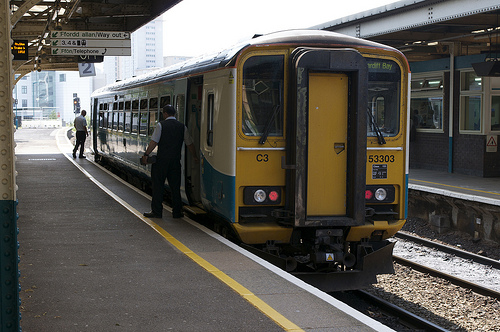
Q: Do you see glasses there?
A: No, there are no glasses.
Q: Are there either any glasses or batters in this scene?
A: No, there are no glasses or batters.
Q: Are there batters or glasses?
A: No, there are no glasses or batters.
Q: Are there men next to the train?
A: Yes, there is a man next to the train.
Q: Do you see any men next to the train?
A: Yes, there is a man next to the train.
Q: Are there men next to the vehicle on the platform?
A: Yes, there is a man next to the train.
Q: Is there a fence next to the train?
A: No, there is a man next to the train.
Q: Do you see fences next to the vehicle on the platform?
A: No, there is a man next to the train.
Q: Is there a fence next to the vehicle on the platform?
A: No, there is a man next to the train.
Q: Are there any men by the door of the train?
A: Yes, there is a man by the door.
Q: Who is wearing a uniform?
A: The man is wearing a uniform.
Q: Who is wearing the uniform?
A: The man is wearing a uniform.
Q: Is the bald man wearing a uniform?
A: Yes, the man is wearing a uniform.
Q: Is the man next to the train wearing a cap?
A: No, the man is wearing a uniform.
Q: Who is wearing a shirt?
A: The man is wearing a shirt.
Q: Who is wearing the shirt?
A: The man is wearing a shirt.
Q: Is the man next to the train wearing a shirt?
A: Yes, the man is wearing a shirt.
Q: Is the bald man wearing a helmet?
A: No, the man is wearing a shirt.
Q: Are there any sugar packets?
A: No, there are no sugar packets.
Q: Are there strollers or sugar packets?
A: No, there are no sugar packets or strollers.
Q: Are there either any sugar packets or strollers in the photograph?
A: No, there are no sugar packets or strollers.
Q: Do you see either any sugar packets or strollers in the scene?
A: No, there are no sugar packets or strollers.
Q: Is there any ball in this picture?
A: No, there are no balls.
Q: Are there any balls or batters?
A: No, there are no balls or batters.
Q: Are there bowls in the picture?
A: No, there are no bowls.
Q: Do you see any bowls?
A: No, there are no bowls.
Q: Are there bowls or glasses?
A: No, there are no bowls or glasses.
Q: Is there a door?
A: Yes, there is a door.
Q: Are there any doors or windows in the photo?
A: Yes, there is a door.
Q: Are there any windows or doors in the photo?
A: Yes, there is a door.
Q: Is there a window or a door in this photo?
A: Yes, there is a door.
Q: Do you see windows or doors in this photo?
A: Yes, there is a door.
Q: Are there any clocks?
A: No, there are no clocks.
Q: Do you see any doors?
A: Yes, there is a door.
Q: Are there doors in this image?
A: Yes, there is a door.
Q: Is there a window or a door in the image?
A: Yes, there is a door.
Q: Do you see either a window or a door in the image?
A: Yes, there is a door.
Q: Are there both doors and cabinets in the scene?
A: No, there is a door but no cabinets.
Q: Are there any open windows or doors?
A: Yes, there is an open door.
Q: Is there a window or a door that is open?
A: Yes, the door is open.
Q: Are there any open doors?
A: Yes, there is an open door.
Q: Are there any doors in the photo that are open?
A: Yes, there is a door that is open.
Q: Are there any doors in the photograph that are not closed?
A: Yes, there is a open door.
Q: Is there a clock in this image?
A: No, there are no clocks.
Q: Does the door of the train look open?
A: Yes, the door is open.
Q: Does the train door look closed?
A: No, the door is open.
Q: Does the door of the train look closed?
A: No, the door is open.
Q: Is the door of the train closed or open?
A: The door is open.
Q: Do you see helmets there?
A: No, there are no helmets.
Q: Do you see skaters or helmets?
A: No, there are no helmets or skaters.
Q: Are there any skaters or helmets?
A: No, there are no helmets or skaters.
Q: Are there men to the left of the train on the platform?
A: Yes, there is a man to the left of the train.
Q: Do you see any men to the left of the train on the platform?
A: Yes, there is a man to the left of the train.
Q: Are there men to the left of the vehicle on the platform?
A: Yes, there is a man to the left of the train.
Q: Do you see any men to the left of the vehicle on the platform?
A: Yes, there is a man to the left of the train.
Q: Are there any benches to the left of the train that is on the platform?
A: No, there is a man to the left of the train.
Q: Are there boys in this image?
A: No, there are no boys.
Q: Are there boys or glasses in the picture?
A: No, there are no boys or glasses.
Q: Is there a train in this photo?
A: Yes, there is a train.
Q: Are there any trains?
A: Yes, there is a train.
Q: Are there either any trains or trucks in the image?
A: Yes, there is a train.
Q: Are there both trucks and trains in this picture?
A: No, there is a train but no trucks.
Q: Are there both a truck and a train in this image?
A: No, there is a train but no trucks.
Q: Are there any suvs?
A: No, there are no suvs.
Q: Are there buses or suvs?
A: No, there are no suvs or buses.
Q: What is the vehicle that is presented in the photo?
A: The vehicle is a train.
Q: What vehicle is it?
A: The vehicle is a train.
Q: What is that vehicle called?
A: This is a train.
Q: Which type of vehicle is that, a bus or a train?
A: This is a train.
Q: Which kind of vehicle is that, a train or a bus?
A: This is a train.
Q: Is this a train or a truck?
A: This is a train.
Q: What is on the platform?
A: The train is on the platform.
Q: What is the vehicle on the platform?
A: The vehicle is a train.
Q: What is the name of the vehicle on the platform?
A: The vehicle is a train.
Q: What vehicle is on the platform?
A: The vehicle is a train.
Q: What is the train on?
A: The train is on the platform.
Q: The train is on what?
A: The train is on the platform.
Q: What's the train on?
A: The train is on the platform.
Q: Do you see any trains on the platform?
A: Yes, there is a train on the platform.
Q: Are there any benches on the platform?
A: No, there is a train on the platform.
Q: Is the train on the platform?
A: Yes, the train is on the platform.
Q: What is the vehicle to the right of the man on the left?
A: The vehicle is a train.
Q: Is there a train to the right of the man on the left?
A: Yes, there is a train to the right of the man.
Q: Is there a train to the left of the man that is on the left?
A: No, the train is to the right of the man.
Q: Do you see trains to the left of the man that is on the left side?
A: No, the train is to the right of the man.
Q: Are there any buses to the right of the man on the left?
A: No, there is a train to the right of the man.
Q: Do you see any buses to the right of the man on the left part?
A: No, there is a train to the right of the man.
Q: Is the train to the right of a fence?
A: No, the train is to the right of the man.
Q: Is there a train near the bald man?
A: Yes, there is a train near the man.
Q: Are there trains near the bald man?
A: Yes, there is a train near the man.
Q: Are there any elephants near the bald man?
A: No, there is a train near the man.